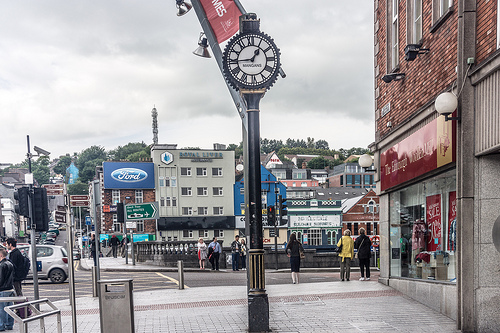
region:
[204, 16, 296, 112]
a street clock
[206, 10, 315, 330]
a post holding a clock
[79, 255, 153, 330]
a trash can on the street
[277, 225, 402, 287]
people standing on the side walk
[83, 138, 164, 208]
a sign for Ford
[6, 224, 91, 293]
a car driving on the street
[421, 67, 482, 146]
a light on the building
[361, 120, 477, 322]
a retail shop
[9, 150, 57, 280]
street traffic signals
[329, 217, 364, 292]
a person wearing a yellow jacket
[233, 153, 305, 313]
the post is black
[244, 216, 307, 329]
the post is black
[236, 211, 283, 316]
the post is black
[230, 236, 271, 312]
the post is black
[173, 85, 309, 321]
the post is black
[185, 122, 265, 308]
the post is black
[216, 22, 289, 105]
clock on a pole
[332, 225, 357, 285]
person with a yellow jacket standing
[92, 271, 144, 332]
trash container on a sidewalk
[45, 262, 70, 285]
rear wheel on a vehicle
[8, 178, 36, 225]
traffic signal on a pole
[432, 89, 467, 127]
light on a building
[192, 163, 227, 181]
windows on a building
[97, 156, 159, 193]
advertising sign on a building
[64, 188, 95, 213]
brown and white sign on a pole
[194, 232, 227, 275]
two people standing on a sidewalk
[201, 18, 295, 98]
The clock is white and black.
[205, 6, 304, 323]
The pole is green.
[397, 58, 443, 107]
The building is brick.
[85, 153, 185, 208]
The sign is blue and white.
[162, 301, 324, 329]
The sidewalk is grey.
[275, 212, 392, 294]
The people are standing on the sidewalk.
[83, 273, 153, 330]
The trash is silver.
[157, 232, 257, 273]
The people are walking across the street.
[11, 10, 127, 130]
It is overcast and cloudy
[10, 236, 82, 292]
The car is driving.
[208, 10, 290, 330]
A clock on a pole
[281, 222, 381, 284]
People waiting to cross the street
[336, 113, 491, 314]
A store front with sale signs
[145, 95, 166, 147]
A tower in the distance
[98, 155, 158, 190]
A Ford sign on a building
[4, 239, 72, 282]
A silver car in the street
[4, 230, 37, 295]
A man with a black backpack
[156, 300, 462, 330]
A brick sidewalk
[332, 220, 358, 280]
A woman with a yellow jacket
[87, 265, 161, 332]
A silver garbage can